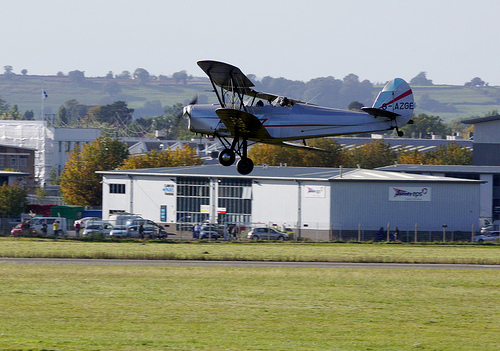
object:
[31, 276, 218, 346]
grass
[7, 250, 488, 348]
field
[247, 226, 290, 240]
car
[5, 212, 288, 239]
group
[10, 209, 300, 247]
cars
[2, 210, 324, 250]
lot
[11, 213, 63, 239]
van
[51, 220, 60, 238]
people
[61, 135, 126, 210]
tree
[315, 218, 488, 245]
fence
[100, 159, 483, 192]
roof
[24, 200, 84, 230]
container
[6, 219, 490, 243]
fence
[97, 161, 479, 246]
building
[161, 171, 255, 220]
windows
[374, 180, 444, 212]
sign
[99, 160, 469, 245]
building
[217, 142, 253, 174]
landing gear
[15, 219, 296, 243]
parking lot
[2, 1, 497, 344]
picture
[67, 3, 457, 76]
sky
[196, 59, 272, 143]
wings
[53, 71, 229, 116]
trees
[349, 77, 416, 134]
tail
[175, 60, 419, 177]
plane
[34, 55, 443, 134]
hill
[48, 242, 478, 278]
runway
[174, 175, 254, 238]
doors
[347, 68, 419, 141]
tailfin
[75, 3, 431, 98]
clouds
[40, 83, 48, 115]
flagpole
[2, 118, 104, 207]
building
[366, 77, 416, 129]
stablizer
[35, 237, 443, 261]
grass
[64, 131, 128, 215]
trees